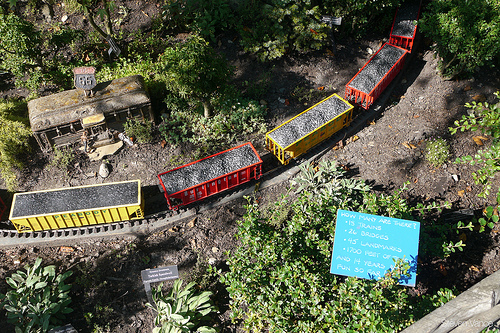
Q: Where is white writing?
A: On blue sign.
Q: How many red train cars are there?
A: Three.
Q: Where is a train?
A: On train tracks.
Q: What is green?
A: Plants.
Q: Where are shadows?
A: On the dirt.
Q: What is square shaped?
A: Blue sign.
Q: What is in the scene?
A: Mini train display.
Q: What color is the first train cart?
A: Yellow.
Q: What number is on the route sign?
A: 66.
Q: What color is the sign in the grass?
A: Blue.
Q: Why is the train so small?
A: Toy.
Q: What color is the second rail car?
A: Red.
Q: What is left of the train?
A: A model diner.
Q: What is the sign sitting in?
A: Grass.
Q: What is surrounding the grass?
A: Dirt.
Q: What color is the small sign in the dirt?
A: Grey.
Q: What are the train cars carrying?
A: Gravel.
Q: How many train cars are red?
A: Three.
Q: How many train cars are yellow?
A: Two.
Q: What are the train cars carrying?
A: Gravel.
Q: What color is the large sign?
A: Blue.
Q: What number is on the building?
A: Sixty-six.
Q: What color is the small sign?
A: Grey.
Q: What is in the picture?
A: A model train set.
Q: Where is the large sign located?
A: In the grass.